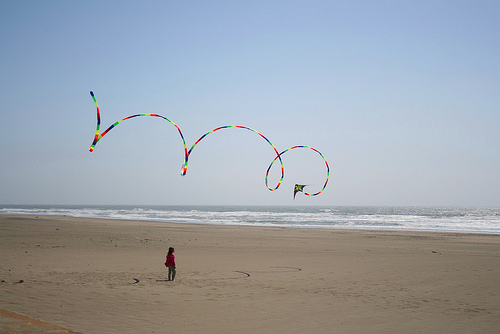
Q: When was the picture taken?
A: Daytime.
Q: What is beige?
A: Sand.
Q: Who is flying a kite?
A: One person.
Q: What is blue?
A: Sky.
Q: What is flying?
A: A kite.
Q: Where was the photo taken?
A: At the beach.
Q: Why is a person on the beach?
A: To fly a kite.